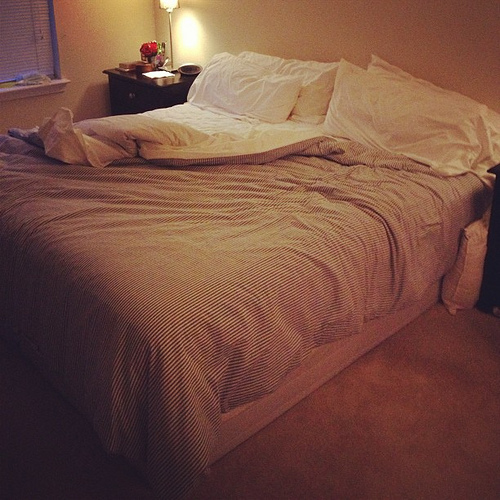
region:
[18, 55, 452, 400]
The bed is not made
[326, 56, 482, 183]
Pillow on a bed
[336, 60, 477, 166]
White pillow on a bed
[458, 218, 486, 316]
Pillow on the floor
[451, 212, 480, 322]
White pillow on the floor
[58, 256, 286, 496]
Corner of the bed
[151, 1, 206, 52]
Light is on in a room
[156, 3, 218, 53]
Light is on in a bedroom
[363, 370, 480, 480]
Carpet on the floor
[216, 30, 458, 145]
Group of pillows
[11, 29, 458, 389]
The bed has not been made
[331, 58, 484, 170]
Pillow on a bed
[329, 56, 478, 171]
White pillow on a bed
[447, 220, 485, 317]
Pillow on the floor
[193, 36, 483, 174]
Four pillows on a bed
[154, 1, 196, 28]
The light is on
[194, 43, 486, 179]
White pillows on the bed.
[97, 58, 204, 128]
A nightstand.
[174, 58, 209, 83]
An oval alarm clock.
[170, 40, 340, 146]
pillows on the bed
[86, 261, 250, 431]
corner of the bed